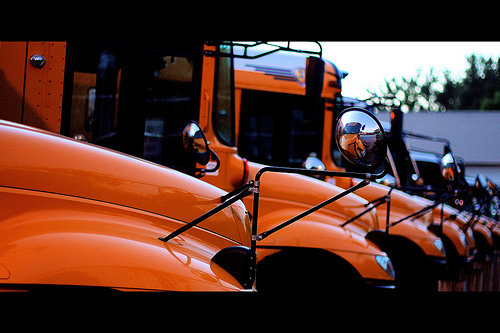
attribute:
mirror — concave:
[331, 103, 388, 171]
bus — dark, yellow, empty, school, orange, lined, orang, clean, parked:
[229, 38, 458, 293]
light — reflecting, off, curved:
[374, 250, 401, 280]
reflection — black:
[337, 119, 368, 160]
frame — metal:
[437, 145, 467, 185]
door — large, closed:
[238, 91, 324, 171]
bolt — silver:
[249, 252, 256, 261]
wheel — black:
[268, 262, 354, 297]